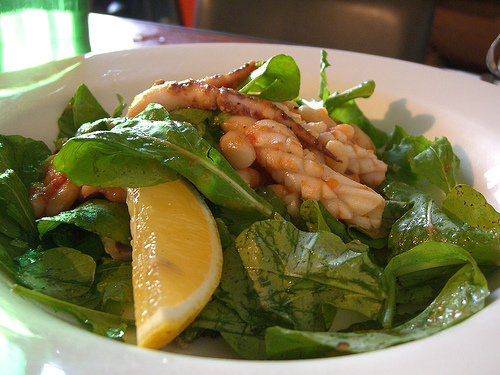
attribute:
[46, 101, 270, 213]
spinach — green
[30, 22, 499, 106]
bowl — white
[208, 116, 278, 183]
bean — brown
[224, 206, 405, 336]
leaf — green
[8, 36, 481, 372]
bowl — white, salad